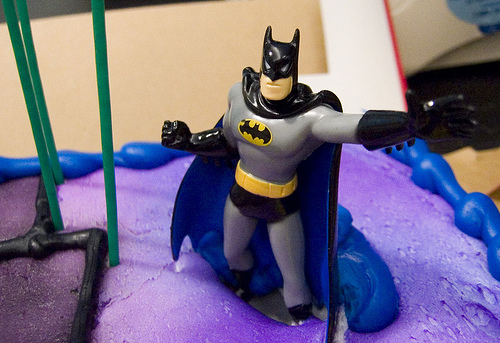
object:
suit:
[170, 66, 344, 342]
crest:
[237, 118, 272, 147]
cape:
[264, 25, 299, 43]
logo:
[237, 118, 273, 146]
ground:
[340, 139, 373, 185]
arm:
[311, 109, 416, 151]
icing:
[0, 137, 500, 343]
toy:
[160, 26, 478, 326]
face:
[260, 42, 293, 100]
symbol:
[237, 118, 272, 146]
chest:
[228, 113, 311, 158]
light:
[269, 51, 273, 56]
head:
[259, 25, 300, 101]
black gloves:
[356, 93, 478, 152]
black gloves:
[161, 112, 236, 154]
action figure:
[160, 25, 480, 326]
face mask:
[258, 25, 300, 82]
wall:
[0, 0, 408, 157]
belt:
[235, 159, 297, 199]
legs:
[268, 194, 306, 293]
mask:
[260, 72, 292, 101]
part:
[376, 120, 427, 138]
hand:
[403, 89, 477, 141]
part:
[121, 48, 184, 101]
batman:
[159, 26, 477, 326]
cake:
[0, 137, 500, 343]